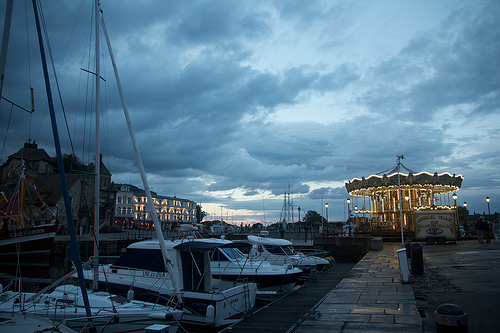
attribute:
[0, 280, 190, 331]
boat — white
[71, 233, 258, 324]
boat — white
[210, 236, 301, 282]
boat — white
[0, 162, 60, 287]
boat — white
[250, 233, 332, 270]
boat — white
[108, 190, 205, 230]
building — curved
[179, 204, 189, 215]
light — bright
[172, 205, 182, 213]
light — bright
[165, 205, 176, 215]
light — bright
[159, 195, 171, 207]
light — bright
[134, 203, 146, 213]
light — bright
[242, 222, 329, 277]
boat — white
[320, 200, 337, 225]
lit post — lamp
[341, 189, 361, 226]
lit post — lamp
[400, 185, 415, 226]
lit post — lamp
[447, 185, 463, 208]
lit post — lamp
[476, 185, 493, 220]
lit post — lamp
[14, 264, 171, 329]
white boat — docked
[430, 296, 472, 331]
bin — lone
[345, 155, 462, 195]
roof — green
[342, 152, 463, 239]
carousel — illuminated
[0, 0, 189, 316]
boat masts — Tall , thin 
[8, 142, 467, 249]
buildings — many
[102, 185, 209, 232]
building — large, white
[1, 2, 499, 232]
sky — full, cloudy, above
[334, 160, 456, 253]
carousel — large , round 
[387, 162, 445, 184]
lights — bright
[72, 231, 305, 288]
boat — white, docked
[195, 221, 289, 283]
boat — white, docked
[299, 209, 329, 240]
tree — tall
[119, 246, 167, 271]
window — blue cover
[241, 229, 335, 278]
boat — white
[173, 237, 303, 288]
boat — white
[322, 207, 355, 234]
posts — long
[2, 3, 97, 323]
sail gear — sail 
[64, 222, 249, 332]
boat — docked, white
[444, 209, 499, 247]
people — standing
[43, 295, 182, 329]
boat — white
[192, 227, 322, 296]
boat — white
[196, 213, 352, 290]
boat — white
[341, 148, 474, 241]
building — circular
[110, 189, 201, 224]
lights — on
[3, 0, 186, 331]
mast — white